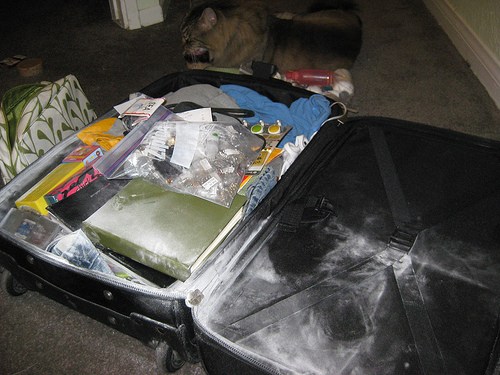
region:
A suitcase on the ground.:
[56, 94, 449, 359]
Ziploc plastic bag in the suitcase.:
[142, 108, 249, 189]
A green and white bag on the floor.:
[11, 72, 101, 134]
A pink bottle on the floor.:
[272, 63, 347, 98]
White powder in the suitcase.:
[261, 204, 423, 336]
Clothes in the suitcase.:
[153, 71, 308, 156]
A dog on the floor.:
[191, 7, 359, 74]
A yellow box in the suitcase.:
[9, 154, 96, 215]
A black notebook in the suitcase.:
[30, 182, 144, 236]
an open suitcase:
[1, 71, 498, 326]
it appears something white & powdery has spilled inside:
[48, 226, 338, 373]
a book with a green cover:
[77, 171, 239, 274]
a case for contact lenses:
[250, 109, 290, 137]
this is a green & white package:
[4, 71, 99, 177]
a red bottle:
[286, 65, 342, 95]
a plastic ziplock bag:
[121, 103, 271, 213]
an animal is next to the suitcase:
[169, 9, 379, 81]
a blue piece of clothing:
[218, 80, 335, 140]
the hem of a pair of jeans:
[230, 155, 274, 229]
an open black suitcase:
[0, 62, 495, 374]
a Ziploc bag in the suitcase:
[92, 106, 268, 206]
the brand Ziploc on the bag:
[142, 125, 171, 165]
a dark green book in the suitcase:
[77, 175, 252, 282]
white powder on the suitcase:
[197, 216, 430, 372]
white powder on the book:
[80, 198, 192, 270]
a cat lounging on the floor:
[175, 0, 364, 82]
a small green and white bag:
[0, 69, 97, 182]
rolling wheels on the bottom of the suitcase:
[5, 272, 187, 372]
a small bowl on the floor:
[17, 54, 43, 78]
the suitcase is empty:
[1, 57, 495, 374]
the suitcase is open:
[0, 56, 498, 363]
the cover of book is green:
[76, 167, 247, 284]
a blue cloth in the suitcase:
[237, 72, 339, 133]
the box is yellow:
[11, 135, 102, 215]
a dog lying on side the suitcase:
[165, 5, 370, 102]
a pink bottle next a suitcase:
[279, 65, 335, 90]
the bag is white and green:
[0, 71, 107, 185]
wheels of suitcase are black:
[1, 265, 183, 373]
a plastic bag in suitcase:
[90, 96, 259, 205]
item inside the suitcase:
[127, 115, 242, 172]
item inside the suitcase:
[105, 199, 203, 275]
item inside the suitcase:
[32, 173, 89, 205]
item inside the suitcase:
[252, 96, 315, 124]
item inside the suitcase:
[272, 64, 337, 85]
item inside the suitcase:
[249, 117, 286, 132]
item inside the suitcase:
[32, 175, 103, 192]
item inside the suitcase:
[9, 74, 92, 141]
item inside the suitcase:
[82, 115, 126, 141]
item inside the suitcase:
[0, 207, 98, 272]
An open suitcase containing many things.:
[0, 64, 489, 369]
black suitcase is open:
[1, 67, 499, 372]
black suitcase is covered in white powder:
[0, 65, 499, 371]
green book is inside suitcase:
[79, 175, 244, 284]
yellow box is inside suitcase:
[15, 160, 83, 221]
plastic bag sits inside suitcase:
[91, 104, 260, 208]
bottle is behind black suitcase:
[286, 68, 339, 89]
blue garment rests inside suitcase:
[215, 82, 331, 146]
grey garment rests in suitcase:
[149, 83, 245, 122]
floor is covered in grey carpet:
[0, 0, 497, 373]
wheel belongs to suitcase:
[154, 340, 185, 374]